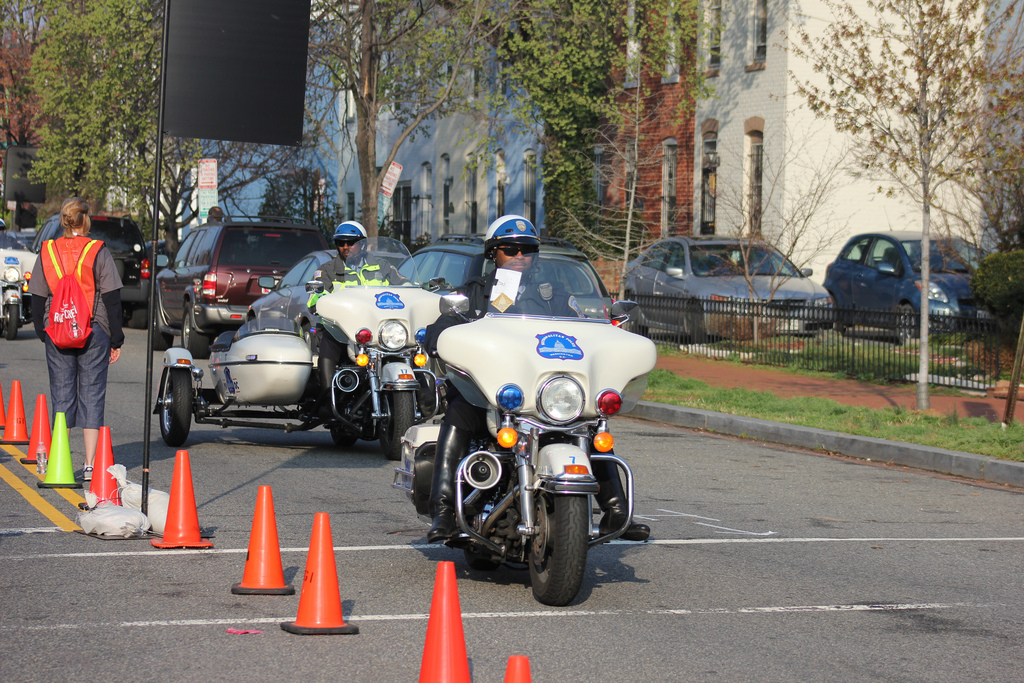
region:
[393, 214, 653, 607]
a policeman riding a motorcycle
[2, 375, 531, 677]
a row of orange security cones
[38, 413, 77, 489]
a lime green security cone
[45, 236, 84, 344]
a woman wearing a red backpack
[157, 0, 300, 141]
a black sign on a pole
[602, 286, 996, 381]
a black metal fence next to a sidewalk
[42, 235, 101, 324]
a woman wearing an orange security vest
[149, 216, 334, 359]
a red SUV driving down the street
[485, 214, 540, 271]
man wearing a white and blue helmet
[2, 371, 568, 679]
a line of traffic cones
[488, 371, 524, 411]
blue light on the front of the bike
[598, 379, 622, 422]
red light on the front of the bike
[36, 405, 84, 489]
bright yellow traffic cone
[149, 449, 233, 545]
orange traffic cone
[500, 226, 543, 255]
dark sunglasses on the face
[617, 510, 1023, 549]
white line on the street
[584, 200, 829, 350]
car is parked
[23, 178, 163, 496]
woman is standing on the street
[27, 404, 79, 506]
Neon green traffic cone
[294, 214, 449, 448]
Cop on a motor cycle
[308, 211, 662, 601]
Two cops riding motorcycles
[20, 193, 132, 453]
Woman wearing an orange safety vest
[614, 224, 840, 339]
Silver parked sedan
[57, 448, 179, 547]
Two sand bags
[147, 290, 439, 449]
A side car on a motorcycle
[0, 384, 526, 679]
line of orange cones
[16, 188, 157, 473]
woman wearing safety vest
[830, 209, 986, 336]
blue car in the parking lot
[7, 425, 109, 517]
yellow lines on the street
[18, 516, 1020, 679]
white lines on the street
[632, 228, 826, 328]
silver car in the parking lot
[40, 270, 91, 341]
red backpack woman is wearing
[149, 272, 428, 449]
motorcycle with a sidecar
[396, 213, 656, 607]
Cop on a motorcycle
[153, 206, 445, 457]
Cop on a motorcycle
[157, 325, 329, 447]
Motorcycle with a sidecar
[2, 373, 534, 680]
Orange traffic cones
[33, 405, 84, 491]
One greenish-yellow traffic cone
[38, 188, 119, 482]
Young lady in safety vest with red backpack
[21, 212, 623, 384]
Cars parked on streetside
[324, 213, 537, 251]
Cops wearing blue helmets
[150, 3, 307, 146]
Back of black street sign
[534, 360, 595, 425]
head light on the motorcycle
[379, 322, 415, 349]
head light on the motorcycle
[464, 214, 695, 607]
A cop on a motorcycle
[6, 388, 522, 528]
Orange and yellow Road cones on the side of the road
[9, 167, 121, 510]
A woman with orange vest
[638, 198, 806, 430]
A gray car in the parking lot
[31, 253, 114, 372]
A woman with the large backpack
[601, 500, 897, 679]
White lines painted on the road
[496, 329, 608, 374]
A blue sticker on front of the motorcycle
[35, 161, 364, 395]
A red truck driving down the road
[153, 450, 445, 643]
cones in a line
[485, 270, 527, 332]
the ticket is white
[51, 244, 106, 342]
the vest is orange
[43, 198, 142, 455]
woman in the vest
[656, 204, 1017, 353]
the cars are on the road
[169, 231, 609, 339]
the cars are parked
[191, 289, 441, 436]
the bike is a two seater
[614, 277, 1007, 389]
a long black fence